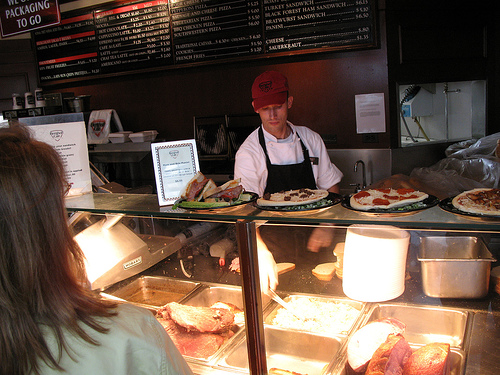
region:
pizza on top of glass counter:
[347, 183, 431, 208]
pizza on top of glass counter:
[253, 189, 327, 205]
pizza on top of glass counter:
[451, 189, 498, 216]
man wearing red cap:
[234, 65, 343, 268]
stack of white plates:
[342, 223, 408, 296]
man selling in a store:
[9, 5, 491, 373]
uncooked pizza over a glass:
[339, 175, 433, 219]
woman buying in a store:
[1, 81, 238, 373]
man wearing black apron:
[210, 58, 360, 276]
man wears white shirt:
[221, 64, 353, 284]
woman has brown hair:
[3, 130, 155, 373]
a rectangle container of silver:
[405, 228, 497, 305]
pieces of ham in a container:
[341, 299, 475, 374]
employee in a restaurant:
[233, 71, 343, 297]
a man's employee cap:
[248, 71, 290, 110]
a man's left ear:
[283, 96, 293, 111]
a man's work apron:
[256, 124, 318, 191]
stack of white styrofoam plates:
[342, 224, 409, 302]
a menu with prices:
[151, 139, 201, 206]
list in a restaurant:
[28, 119, 93, 199]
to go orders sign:
[1, 0, 59, 38]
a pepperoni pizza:
[350, 186, 430, 211]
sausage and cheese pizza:
[257, 185, 327, 207]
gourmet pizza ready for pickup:
[258, 185, 329, 206]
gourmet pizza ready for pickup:
[352, 185, 424, 207]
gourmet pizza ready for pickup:
[452, 187, 499, 221]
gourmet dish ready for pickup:
[176, 170, 247, 210]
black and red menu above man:
[36, 3, 381, 85]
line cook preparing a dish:
[233, 60, 345, 295]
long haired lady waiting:
[0, 120, 205, 372]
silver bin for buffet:
[415, 233, 495, 300]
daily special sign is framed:
[147, 139, 204, 207]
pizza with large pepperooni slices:
[350, 185, 427, 210]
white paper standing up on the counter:
[150, 138, 201, 205]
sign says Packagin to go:
[0, 0, 61, 38]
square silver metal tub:
[417, 238, 494, 298]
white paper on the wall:
[354, 92, 384, 134]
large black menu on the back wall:
[31, 1, 383, 87]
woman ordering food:
[2, 122, 190, 372]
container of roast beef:
[155, 302, 242, 361]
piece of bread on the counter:
[311, 260, 336, 280]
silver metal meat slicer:
[63, 206, 180, 290]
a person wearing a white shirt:
[208, 66, 343, 232]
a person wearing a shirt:
[229, 63, 341, 218]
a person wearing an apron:
[232, 58, 364, 260]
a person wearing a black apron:
[217, 49, 360, 269]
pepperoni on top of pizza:
[351, 189, 370, 198]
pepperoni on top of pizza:
[374, 186, 392, 194]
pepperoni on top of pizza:
[395, 184, 414, 195]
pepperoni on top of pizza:
[371, 196, 390, 205]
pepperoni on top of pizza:
[382, 192, 400, 200]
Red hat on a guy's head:
[241, 61, 298, 136]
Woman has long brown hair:
[0, 110, 200, 371]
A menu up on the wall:
[25, 0, 385, 95]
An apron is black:
[246, 116, 321, 196]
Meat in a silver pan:
[327, 316, 467, 371]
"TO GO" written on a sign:
[10, 5, 45, 32]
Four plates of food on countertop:
[170, 167, 495, 234]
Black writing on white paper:
[145, 130, 205, 210]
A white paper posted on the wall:
[345, 85, 391, 140]